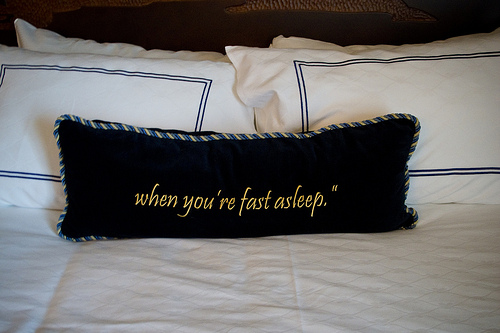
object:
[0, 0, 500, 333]
bed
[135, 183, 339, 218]
gold words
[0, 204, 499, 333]
white sheets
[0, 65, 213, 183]
blue lines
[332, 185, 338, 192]
quotation marks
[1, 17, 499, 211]
pillows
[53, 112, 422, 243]
blue and gold trim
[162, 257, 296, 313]
wrinkled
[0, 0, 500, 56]
brown headboard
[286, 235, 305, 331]
designed lines